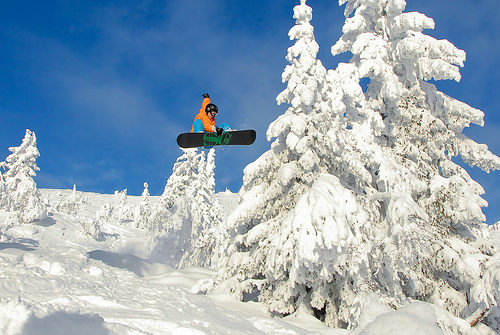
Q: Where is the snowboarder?
A: In mid air.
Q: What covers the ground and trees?
A: Snow.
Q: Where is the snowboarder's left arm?
A: Extended up.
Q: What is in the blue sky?
A: Sparsely spread clouds.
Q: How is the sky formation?
A: Full of clouds.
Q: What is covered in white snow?
A: The tree.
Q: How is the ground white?
A: Covered by snow.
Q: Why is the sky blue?
A: Less cloudy.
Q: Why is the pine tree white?
A: Covered by snow.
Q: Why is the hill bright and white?
A: Covered in snow.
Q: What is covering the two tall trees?
A: A thick coat of snow.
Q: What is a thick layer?
A: Snow on the the hill and trees.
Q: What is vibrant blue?
A: The sky.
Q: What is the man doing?
A: Snowboarding.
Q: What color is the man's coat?
A: Orange.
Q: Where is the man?
A: In the air.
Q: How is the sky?
A: Clear.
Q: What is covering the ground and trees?
A: Snow.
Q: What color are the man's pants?
A: Blue.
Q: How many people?
A: One.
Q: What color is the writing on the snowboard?
A: Green.